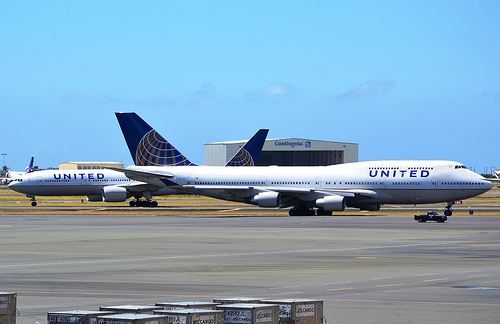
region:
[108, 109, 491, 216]
Large white plane on runway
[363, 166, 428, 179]
UNITED logo on airplane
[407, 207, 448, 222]
Truck parked next to airplane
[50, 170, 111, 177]
UNITED logo on airplane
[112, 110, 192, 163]
Large blue tail on airplane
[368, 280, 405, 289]
Small yellow traffic line on runway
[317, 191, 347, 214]
Large white jet engine under wing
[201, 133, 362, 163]
Large white building behind airplane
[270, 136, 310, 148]
Large logo on building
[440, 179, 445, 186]
Small window next to door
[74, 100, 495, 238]
plane taxiing on tarmac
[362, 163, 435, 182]
brand name of an airline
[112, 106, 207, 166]
tail fin of blue and gold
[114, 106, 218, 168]
tail fin of gold and blue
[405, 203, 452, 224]
pick-up truck looking small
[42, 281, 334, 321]
carts for handling food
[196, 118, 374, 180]
a hangar of some size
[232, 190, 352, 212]
two engines hanging on a wing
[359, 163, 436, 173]
windows for the upstairs area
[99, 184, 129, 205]
jet engine on the second plane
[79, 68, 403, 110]
Light clouds in blue sky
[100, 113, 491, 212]
White jet plane on tarmac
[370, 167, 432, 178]
Blue letters on white plane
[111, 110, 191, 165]
Blue tail on white plane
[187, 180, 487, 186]
Long row of small windows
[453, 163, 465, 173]
Pilot windows on front of plane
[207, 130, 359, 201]
White airplane hangar beside runway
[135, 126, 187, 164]
Grid filled circle on tail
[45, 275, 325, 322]
Brown cargo boxes on tarmac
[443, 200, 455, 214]
Landing gear on airplane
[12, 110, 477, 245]
Two planes near each other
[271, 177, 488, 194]
Lower windows of plane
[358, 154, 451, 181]
Upper windows are higher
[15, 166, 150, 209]
United plane in background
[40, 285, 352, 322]
Baggage car in foreground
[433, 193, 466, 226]
Front wheel of airplane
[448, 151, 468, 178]
Cockpit window of airplane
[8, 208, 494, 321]
Runway is gray and concrete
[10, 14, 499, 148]
Sky is clear and blue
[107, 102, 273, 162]
Two tailwings have globe on them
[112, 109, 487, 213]
a large blue and white plane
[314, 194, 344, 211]
an engine on a plane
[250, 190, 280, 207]
an engine on a plane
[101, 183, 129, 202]
an engine on a plane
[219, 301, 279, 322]
a small silver truck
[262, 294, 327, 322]
a small silver truck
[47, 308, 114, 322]
a small silver truck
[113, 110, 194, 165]
blue tail of a plane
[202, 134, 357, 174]
white hanger in the distance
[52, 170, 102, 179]
word "united" on a plane